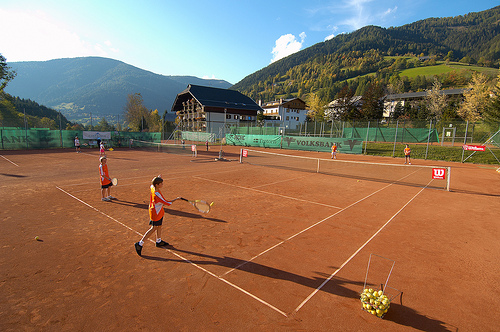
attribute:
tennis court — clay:
[2, 138, 500, 331]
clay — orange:
[4, 141, 500, 331]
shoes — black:
[133, 238, 170, 255]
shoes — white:
[103, 200, 116, 204]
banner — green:
[227, 135, 364, 153]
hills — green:
[3, 3, 500, 130]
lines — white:
[3, 154, 444, 317]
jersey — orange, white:
[101, 163, 112, 187]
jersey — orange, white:
[149, 189, 173, 221]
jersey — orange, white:
[404, 149, 410, 156]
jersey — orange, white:
[333, 145, 338, 153]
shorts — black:
[148, 217, 164, 229]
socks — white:
[137, 238, 163, 246]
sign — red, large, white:
[463, 144, 485, 153]